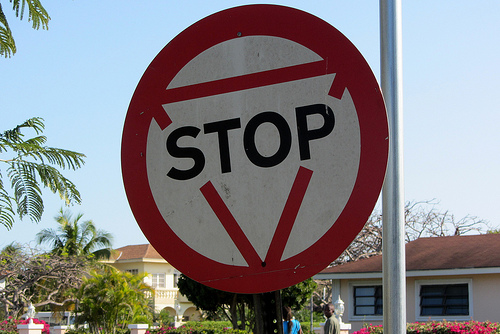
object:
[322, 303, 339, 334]
boy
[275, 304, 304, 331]
woman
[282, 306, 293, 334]
ponytail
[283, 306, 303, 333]
person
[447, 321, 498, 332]
flowers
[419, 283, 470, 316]
window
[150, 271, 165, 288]
window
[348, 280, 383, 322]
window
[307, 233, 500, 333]
home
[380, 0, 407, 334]
pole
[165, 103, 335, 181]
sign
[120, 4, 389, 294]
sign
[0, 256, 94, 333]
trees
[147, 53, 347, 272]
triangle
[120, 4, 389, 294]
circle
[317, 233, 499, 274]
roof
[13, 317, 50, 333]
flowers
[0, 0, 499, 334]
clear day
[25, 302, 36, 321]
statue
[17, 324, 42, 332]
stand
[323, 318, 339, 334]
top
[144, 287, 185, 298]
balcony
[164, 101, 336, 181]
word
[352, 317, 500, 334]
bush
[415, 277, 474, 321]
trim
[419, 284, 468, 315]
slats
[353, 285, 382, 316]
slats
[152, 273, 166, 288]
slats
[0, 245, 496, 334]
street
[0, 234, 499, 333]
city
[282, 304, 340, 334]
two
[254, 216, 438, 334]
camera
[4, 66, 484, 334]
camera